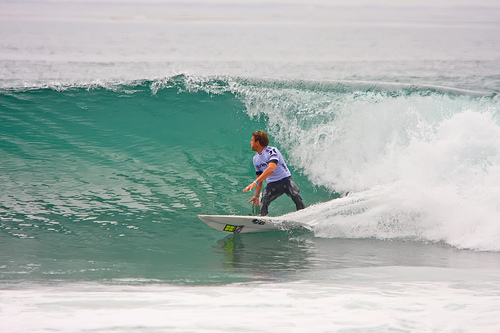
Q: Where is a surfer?
A: In the ocean.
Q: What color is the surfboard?
A: White.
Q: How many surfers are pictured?
A: One.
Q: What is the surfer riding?
A: A wave.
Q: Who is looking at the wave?
A: A surfer.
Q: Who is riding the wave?
A: A surfer.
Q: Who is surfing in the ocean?
A: A man.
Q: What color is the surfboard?
A: White.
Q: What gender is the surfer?
A: A man.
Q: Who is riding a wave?
A: A man.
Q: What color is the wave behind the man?
A: White.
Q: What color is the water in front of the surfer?
A: Green.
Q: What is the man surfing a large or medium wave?
A: Medium.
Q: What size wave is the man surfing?
A: Medium.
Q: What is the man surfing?
A: Medium wave.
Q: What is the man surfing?
A: Medium wave.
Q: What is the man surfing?
A: Medium wave.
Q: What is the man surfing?
A: Medium wave.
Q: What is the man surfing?
A: Medium wave.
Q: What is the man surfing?
A: Medium wave.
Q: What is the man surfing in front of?
A: The inside of a large green and blue wave.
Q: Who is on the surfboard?
A: A man in a blue shirt.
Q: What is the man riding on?
A: A surfboard.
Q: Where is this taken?
A: In the ocean.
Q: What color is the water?
A: Aqua.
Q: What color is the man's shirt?
A: Blue.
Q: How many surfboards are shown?
A: One.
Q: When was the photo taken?
A: Day time.